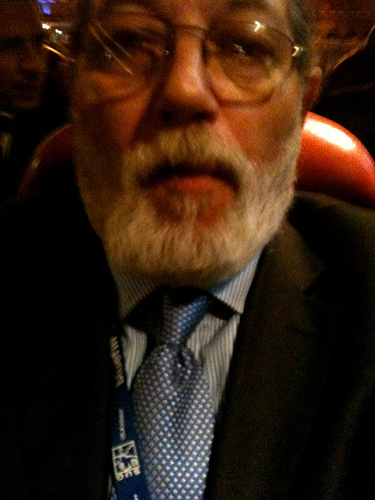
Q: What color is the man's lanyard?
A: Blue.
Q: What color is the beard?
A: White.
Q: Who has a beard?
A: The subject.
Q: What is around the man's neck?
A: A necktie.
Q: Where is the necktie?
A: In the man's collar.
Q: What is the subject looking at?
A: The camera.